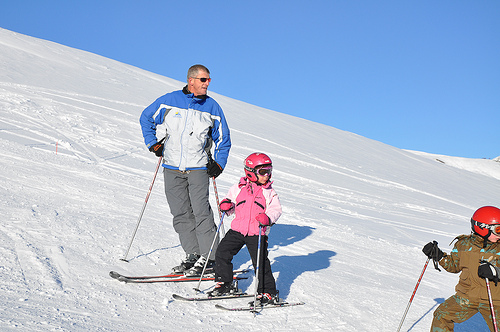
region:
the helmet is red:
[243, 149, 275, 181]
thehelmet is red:
[458, 203, 495, 220]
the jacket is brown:
[446, 243, 496, 320]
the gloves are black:
[421, 235, 452, 273]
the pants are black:
[219, 233, 279, 296]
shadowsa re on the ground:
[278, 215, 331, 295]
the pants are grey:
[164, 169, 224, 263]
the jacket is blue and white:
[138, 98, 231, 172]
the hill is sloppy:
[27, 33, 442, 313]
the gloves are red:
[252, 202, 281, 249]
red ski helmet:
[466, 203, 496, 238]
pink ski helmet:
[241, 150, 271, 181]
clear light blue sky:
[215, 5, 492, 90]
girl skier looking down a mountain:
[172, 150, 302, 310]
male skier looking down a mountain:
[111, 62, 229, 282]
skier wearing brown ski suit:
[422, 205, 495, 328]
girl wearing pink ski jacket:
[217, 177, 279, 232]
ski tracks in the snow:
[280, 140, 452, 231]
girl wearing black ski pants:
[212, 230, 278, 295]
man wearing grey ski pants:
[161, 165, 218, 257]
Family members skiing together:
[135, 60, 498, 327]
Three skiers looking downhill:
[139, 57, 497, 328]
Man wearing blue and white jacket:
[140, 62, 236, 174]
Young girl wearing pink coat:
[219, 151, 286, 237]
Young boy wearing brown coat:
[421, 201, 498, 307]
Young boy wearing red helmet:
[465, 200, 499, 244]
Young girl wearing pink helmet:
[238, 148, 278, 183]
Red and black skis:
[105, 268, 207, 281]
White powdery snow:
[7, 186, 108, 329]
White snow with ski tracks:
[1, 76, 123, 172]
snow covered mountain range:
[297, 114, 373, 169]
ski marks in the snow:
[39, 253, 88, 281]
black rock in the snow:
[430, 152, 456, 173]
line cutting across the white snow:
[309, 149, 431, 190]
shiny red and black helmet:
[465, 205, 493, 235]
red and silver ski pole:
[409, 249, 436, 296]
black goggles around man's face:
[184, 71, 236, 97]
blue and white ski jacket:
[151, 96, 237, 178]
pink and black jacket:
[219, 179, 288, 251]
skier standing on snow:
[122, 72, 312, 303]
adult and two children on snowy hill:
[0, 18, 496, 328]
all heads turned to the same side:
[107, 57, 493, 322]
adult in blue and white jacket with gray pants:
[105, 60, 230, 280]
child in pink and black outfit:
[206, 146, 276, 301]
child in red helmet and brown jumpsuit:
[420, 201, 495, 326]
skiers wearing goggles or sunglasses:
[140, 60, 496, 240]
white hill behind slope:
[355, 117, 496, 189]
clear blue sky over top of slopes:
[0, 1, 495, 183]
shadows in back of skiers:
[220, 215, 336, 305]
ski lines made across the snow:
[5, 77, 482, 253]